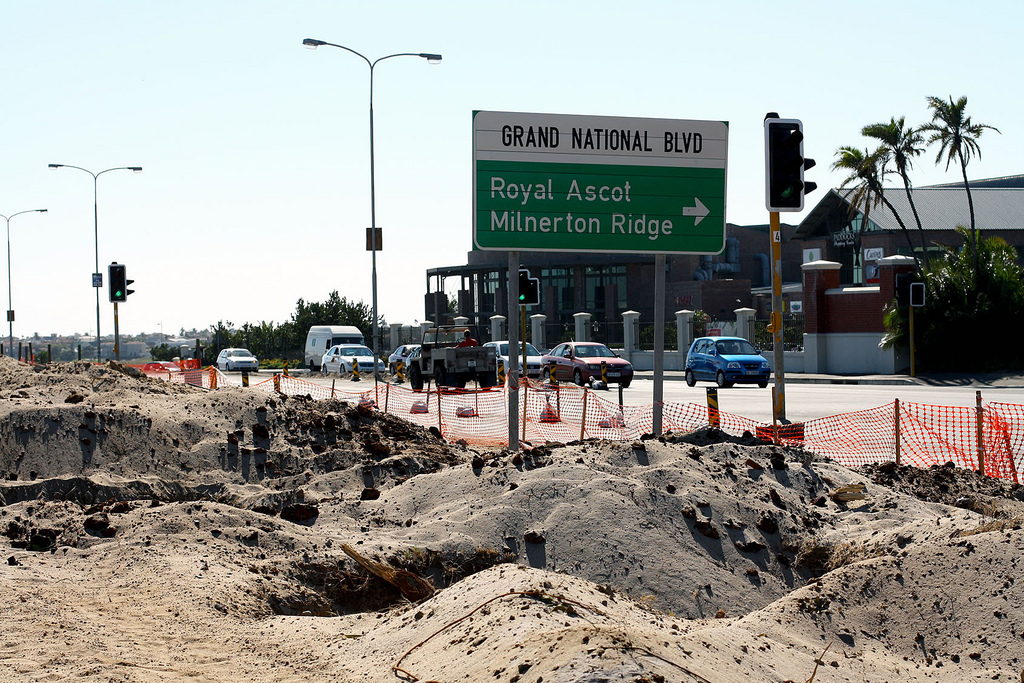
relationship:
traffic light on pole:
[761, 106, 818, 215] [766, 216, 789, 426]